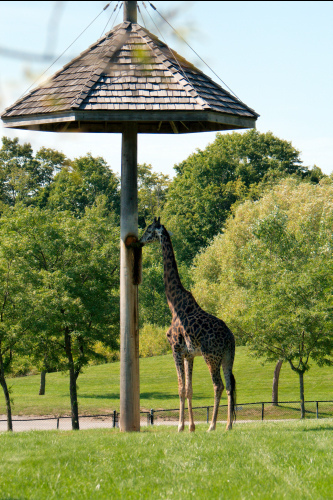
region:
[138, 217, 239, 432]
tall giraffe on park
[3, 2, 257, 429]
hut in a park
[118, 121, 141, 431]
large gray pole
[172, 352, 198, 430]
two front legs of giraffe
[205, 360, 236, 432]
back legs of giraffe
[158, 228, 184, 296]
large neck of giraffe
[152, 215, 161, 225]
two small ears of giraffe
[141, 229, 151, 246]
little trunk of giraffe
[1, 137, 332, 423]
big green trees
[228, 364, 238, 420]
large hairy tail of giraffe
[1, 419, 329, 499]
Grass beneath the giraffe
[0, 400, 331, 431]
A small fence behind the giraffe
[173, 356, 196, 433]
The front legs of the giraffe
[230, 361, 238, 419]
The tail of the giraffe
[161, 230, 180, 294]
The giraffe has a long neck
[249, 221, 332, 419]
A tree near the fence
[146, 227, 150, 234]
The left eye of the giraffe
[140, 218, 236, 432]
The giraffe is eating some food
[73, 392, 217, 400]
A shadow in the field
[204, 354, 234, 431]
The back legs of the giraffe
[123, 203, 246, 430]
giraffe stading near the post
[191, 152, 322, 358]
trees with branches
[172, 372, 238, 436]
leg of the giraffe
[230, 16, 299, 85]
blue color sky with clouds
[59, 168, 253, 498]
a giraffe standing in the green grass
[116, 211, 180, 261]
head of the giraffe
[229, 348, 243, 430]
tail of the giraffe and fringes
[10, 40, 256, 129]
tent for giraffe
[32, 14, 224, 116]
top of the giraffe tent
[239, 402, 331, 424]
green color coated metal fencing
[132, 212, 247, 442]
A giraffe eating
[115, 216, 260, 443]
A giraffe standing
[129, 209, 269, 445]
A giraffe in the grass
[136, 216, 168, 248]
The head of the zebra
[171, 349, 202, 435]
The two front legs of the giraffe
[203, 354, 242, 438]
The two back legs of the giraffe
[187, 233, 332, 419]
A large tree in the background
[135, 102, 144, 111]
A shingle on a roof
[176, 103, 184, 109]
A shingle on a roof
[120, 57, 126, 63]
A shingle on the roof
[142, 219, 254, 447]
Giraffe standing in the zoo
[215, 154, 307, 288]
Lot of trees with branches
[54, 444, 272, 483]
Green color grass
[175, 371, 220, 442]
Long legs of the giraffe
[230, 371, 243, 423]
Tail with fringes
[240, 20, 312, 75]
A blue color sky with clouds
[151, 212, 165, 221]
Short knobbed horn in the giraffe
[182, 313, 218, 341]
Brown polygons on a cream color backround of the giraffe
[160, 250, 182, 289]
Neck of the giraffe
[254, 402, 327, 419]
Fencing near the grass